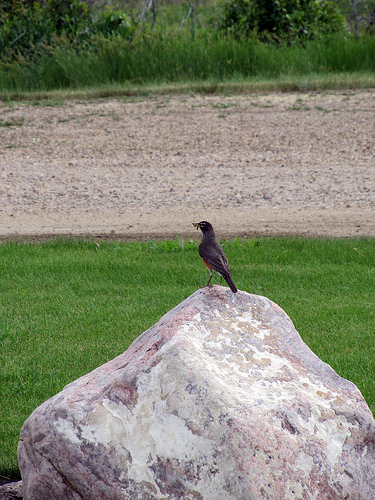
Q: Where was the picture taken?
A: It was taken at the road.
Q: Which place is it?
A: It is a road.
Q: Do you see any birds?
A: Yes, there is a bird.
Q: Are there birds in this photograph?
A: Yes, there is a bird.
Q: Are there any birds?
A: Yes, there is a bird.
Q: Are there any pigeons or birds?
A: Yes, there is a bird.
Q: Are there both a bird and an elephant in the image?
A: No, there is a bird but no elephants.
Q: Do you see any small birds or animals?
A: Yes, there is a small bird.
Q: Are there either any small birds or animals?
A: Yes, there is a small bird.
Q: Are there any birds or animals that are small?
A: Yes, the bird is small.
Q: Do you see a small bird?
A: Yes, there is a small bird.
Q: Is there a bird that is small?
A: Yes, there is a bird that is small.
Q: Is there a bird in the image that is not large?
A: Yes, there is a small bird.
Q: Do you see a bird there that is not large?
A: Yes, there is a small bird.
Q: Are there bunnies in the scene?
A: No, there are no bunnies.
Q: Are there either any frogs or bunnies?
A: No, there are no bunnies or frogs.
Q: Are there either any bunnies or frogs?
A: No, there are no bunnies or frogs.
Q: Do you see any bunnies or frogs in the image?
A: No, there are no bunnies or frogs.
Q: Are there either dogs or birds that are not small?
A: No, there is a bird but it is small.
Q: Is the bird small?
A: Yes, the bird is small.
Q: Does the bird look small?
A: Yes, the bird is small.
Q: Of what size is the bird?
A: The bird is small.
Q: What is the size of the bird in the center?
A: The bird is small.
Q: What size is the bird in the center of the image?
A: The bird is small.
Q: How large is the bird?
A: The bird is small.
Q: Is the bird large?
A: No, the bird is small.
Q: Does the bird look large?
A: No, the bird is small.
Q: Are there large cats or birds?
A: No, there is a bird but it is small.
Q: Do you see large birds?
A: No, there is a bird but it is small.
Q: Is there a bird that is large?
A: No, there is a bird but it is small.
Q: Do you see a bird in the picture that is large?
A: No, there is a bird but it is small.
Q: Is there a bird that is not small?
A: No, there is a bird but it is small.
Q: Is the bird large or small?
A: The bird is small.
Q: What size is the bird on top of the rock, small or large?
A: The bird is small.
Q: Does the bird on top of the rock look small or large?
A: The bird is small.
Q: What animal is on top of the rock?
A: The animal is a bird.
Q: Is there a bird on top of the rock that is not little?
A: Yes, there is a bird on top of the rock.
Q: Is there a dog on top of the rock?
A: No, there is a bird on top of the rock.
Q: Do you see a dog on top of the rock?
A: No, there is a bird on top of the rock.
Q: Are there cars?
A: No, there are no cars.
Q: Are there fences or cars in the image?
A: No, there are no cars or fences.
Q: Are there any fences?
A: No, there are no fences.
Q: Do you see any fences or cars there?
A: No, there are no fences or cars.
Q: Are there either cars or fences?
A: No, there are no fences or cars.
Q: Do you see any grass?
A: Yes, there is grass.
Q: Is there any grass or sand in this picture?
A: Yes, there is grass.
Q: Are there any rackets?
A: No, there are no rackets.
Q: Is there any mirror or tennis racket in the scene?
A: No, there are no rackets or mirrors.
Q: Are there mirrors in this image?
A: No, there are no mirrors.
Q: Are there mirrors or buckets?
A: No, there are no mirrors or buckets.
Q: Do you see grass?
A: Yes, there is grass.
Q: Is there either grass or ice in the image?
A: Yes, there is grass.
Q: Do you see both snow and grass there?
A: No, there is grass but no snow.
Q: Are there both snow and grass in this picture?
A: No, there is grass but no snow.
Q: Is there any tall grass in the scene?
A: Yes, there is tall grass.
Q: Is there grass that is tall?
A: Yes, there is grass that is tall.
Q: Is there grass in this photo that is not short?
A: Yes, there is tall grass.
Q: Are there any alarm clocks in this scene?
A: No, there are no alarm clocks.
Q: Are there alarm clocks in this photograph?
A: No, there are no alarm clocks.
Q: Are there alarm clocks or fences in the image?
A: No, there are no alarm clocks or fences.